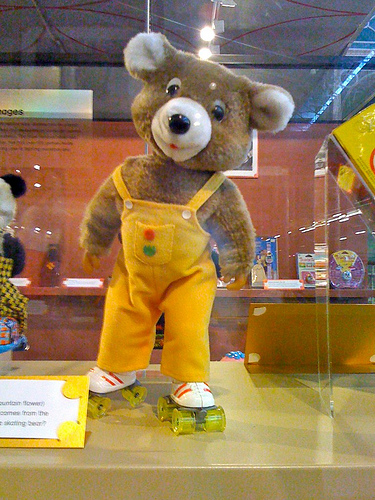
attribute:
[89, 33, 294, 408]
bear — stuffed, large, brown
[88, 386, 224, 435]
skates — yellow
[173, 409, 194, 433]
wheel — yellow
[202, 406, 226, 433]
wheel — yellow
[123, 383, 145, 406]
wheel — yellow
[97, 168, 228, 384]
outfit — checked, yellow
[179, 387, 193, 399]
stripe — orange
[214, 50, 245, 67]
reflection — ceiling light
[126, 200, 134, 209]
button — white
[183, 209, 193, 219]
button — white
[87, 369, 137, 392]
shoe — white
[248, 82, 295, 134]
ear — large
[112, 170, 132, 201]
strap — yellow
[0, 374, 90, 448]
placard — paper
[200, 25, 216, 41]
light — on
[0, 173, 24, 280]
bear — panda, stuffed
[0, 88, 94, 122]
sign — clear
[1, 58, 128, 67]
bar — black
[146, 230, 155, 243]
button — orange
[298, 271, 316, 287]
watch — digital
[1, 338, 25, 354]
seat — blue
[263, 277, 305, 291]
sign — orange